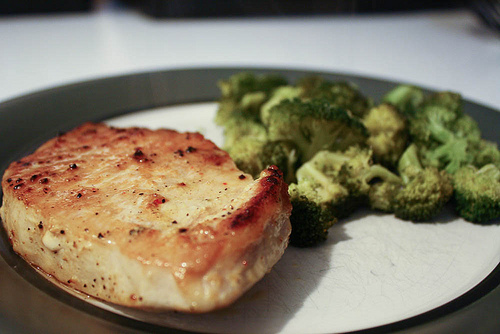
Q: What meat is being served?
A: Pork.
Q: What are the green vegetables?
A: Broccoli.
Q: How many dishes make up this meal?
A: 2.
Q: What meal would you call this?
A: Dinner.